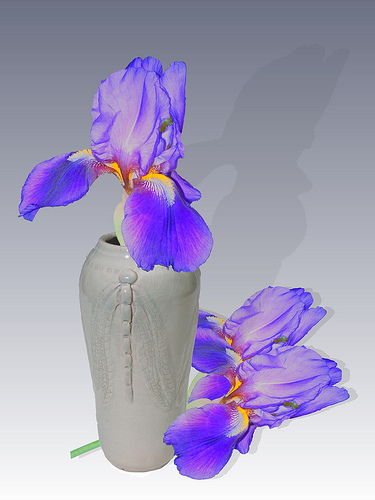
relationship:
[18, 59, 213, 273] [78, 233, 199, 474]
flower are in vase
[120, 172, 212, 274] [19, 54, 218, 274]
petal on flower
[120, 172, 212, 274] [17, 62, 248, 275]
petal on flower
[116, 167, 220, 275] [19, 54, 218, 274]
petal on flower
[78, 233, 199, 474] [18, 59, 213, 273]
vase has flower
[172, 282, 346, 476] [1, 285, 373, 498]
petals are on ground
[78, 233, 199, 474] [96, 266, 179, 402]
vase has designs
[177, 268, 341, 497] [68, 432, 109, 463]
flower has stem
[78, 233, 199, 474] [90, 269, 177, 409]
vase has design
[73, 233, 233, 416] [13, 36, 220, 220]
vase has iris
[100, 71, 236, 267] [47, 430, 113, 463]
flower has stem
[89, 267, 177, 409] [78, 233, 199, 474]
design on vase